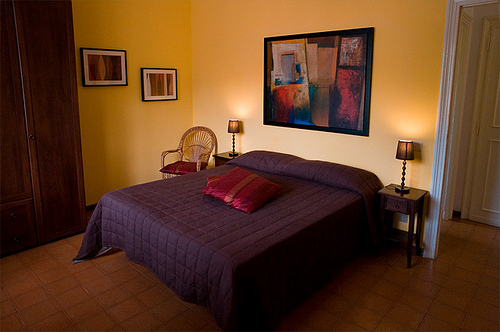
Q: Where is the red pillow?
A: Middle.